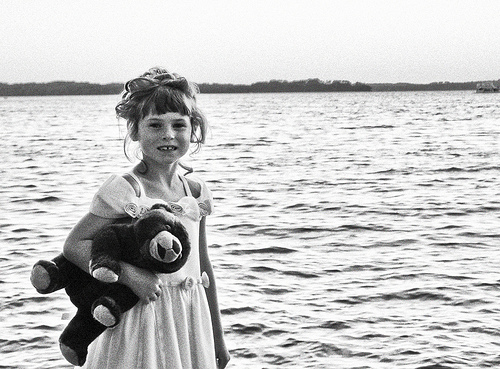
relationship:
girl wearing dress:
[45, 51, 314, 356] [83, 168, 214, 365]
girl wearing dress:
[62, 65, 233, 368] [104, 171, 225, 367]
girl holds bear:
[62, 65, 233, 368] [32, 201, 185, 367]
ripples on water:
[1, 81, 498, 367] [1, 94, 498, 367]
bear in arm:
[29, 202, 191, 367] [56, 197, 158, 294]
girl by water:
[62, 65, 233, 368] [1, 94, 498, 367]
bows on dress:
[178, 270, 225, 292] [84, 169, 228, 367]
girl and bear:
[62, 65, 233, 368] [45, 210, 189, 352]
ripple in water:
[339, 122, 394, 129] [1, 94, 498, 367]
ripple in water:
[433, 165, 498, 173] [1, 94, 498, 367]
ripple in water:
[436, 222, 462, 232] [1, 94, 498, 367]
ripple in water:
[403, 285, 445, 300] [1, 94, 498, 367]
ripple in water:
[310, 315, 348, 331] [1, 94, 498, 367]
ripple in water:
[394, 342, 421, 349] [253, 108, 478, 317]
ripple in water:
[293, 173, 377, 190] [206, 98, 485, 360]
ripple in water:
[204, 241, 302, 255] [1, 94, 498, 367]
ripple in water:
[230, 242, 312, 267] [244, 190, 478, 337]